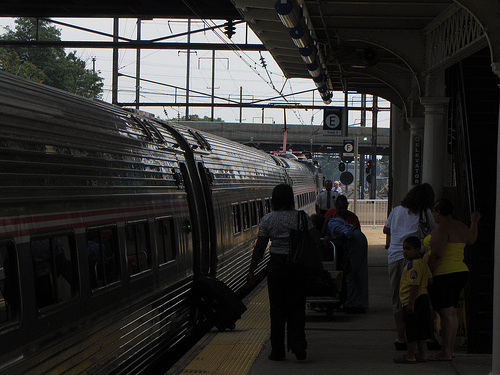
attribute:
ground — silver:
[446, 182, 459, 202]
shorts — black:
[394, 289, 449, 349]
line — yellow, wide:
[213, 271, 261, 359]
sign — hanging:
[340, 136, 355, 163]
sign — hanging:
[326, 110, 346, 137]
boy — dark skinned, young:
[389, 230, 431, 363]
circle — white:
[326, 114, 340, 128]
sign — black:
[323, 106, 343, 130]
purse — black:
[297, 205, 320, 274]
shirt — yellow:
[425, 233, 470, 275]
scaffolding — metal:
[110, 19, 387, 113]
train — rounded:
[3, 65, 325, 374]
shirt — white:
[313, 189, 341, 210]